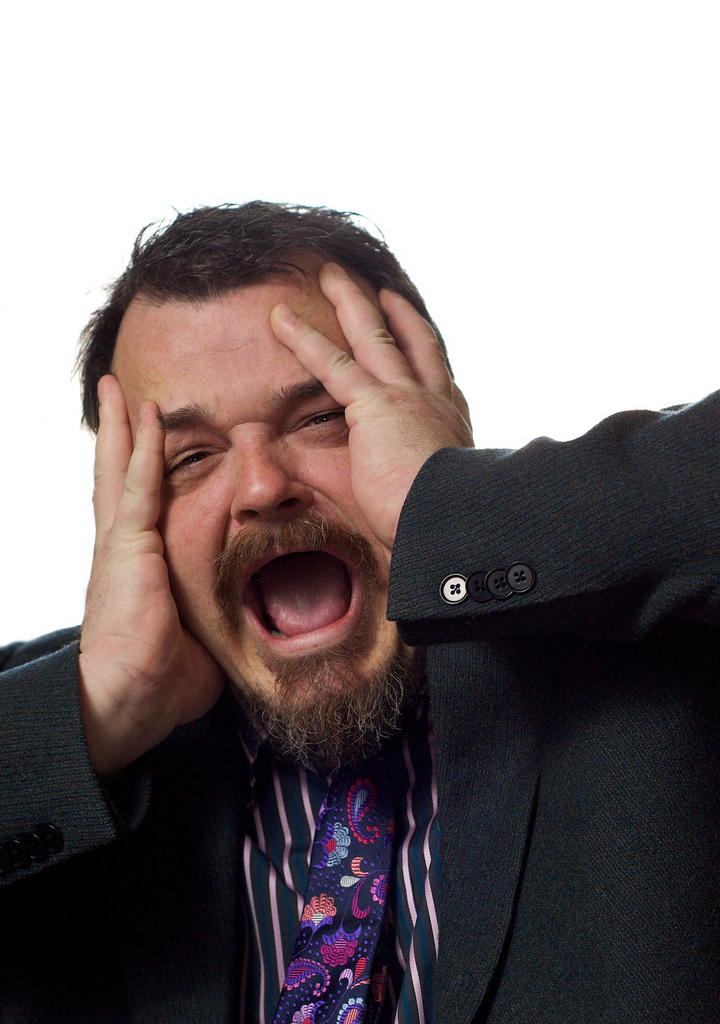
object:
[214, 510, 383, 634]
mustache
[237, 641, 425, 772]
chin hair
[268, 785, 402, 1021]
tie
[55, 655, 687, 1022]
shirt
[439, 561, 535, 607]
buttons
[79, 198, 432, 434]
hair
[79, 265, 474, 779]
hands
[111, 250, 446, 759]
face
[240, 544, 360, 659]
mouth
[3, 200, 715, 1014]
man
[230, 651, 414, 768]
beard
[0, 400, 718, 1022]
jacket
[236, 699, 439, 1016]
shirt